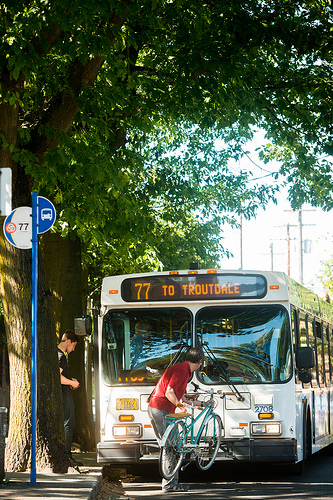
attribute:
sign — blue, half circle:
[34, 194, 59, 236]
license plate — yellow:
[110, 394, 149, 416]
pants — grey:
[145, 404, 189, 489]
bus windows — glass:
[112, 306, 270, 376]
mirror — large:
[74, 318, 88, 335]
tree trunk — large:
[4, 263, 32, 331]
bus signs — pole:
[0, 185, 61, 254]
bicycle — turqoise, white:
[152, 385, 227, 481]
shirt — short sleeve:
[143, 354, 214, 406]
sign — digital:
[127, 275, 260, 299]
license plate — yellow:
[116, 399, 140, 411]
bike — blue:
[159, 380, 235, 480]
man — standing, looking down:
[51, 322, 81, 383]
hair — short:
[183, 343, 205, 363]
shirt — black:
[54, 346, 74, 402]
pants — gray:
[60, 396, 83, 469]